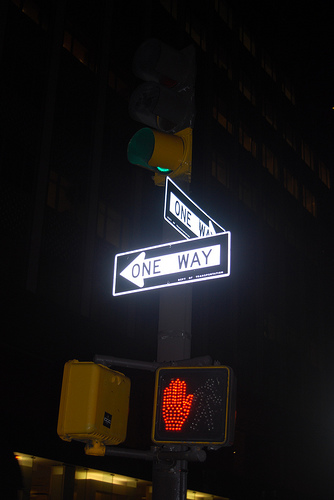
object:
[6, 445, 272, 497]
frame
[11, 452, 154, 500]
lights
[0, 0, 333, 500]
building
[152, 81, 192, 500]
pole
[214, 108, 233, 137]
window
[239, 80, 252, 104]
window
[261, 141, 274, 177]
window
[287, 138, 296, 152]
window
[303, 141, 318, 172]
window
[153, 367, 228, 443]
sign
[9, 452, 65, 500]
window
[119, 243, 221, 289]
arrow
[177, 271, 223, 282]
writing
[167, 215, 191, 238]
writing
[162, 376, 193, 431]
hand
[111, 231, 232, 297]
street signs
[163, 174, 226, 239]
street signs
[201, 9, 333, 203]
bank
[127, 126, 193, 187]
light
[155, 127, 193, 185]
yellow backing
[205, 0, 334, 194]
ground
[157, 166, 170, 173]
green light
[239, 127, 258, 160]
window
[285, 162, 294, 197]
window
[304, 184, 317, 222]
window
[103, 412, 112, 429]
sticker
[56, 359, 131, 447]
light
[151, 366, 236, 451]
light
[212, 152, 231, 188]
windows